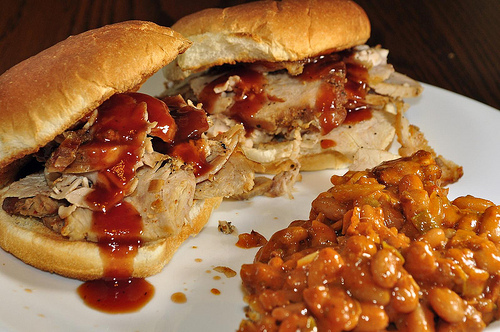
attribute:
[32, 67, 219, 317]
bbq — white 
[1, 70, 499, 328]
plate — white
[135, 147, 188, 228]
meat — in hunk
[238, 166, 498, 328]
baked beans — served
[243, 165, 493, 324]
bean — baked 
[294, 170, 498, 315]
bean — baked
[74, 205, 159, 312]
bbq sauce — dripping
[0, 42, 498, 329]
plate — round, white